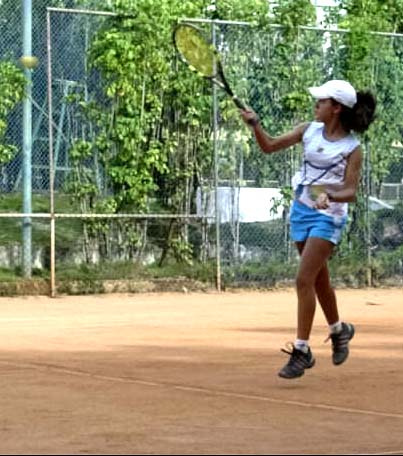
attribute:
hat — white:
[312, 71, 358, 110]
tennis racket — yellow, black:
[171, 23, 259, 127]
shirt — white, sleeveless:
[290, 115, 368, 220]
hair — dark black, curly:
[334, 90, 382, 136]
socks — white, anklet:
[292, 338, 306, 351]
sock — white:
[290, 339, 307, 354]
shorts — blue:
[288, 185, 350, 248]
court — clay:
[49, 334, 286, 449]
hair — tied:
[346, 92, 382, 135]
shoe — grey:
[330, 319, 355, 369]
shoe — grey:
[278, 346, 317, 381]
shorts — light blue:
[289, 197, 350, 247]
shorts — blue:
[286, 192, 350, 249]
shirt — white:
[289, 120, 359, 219]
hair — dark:
[336, 91, 378, 137]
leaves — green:
[112, 34, 144, 97]